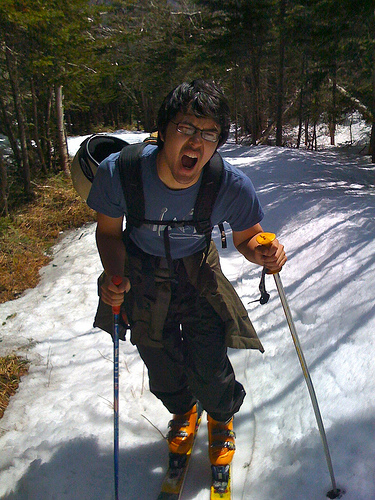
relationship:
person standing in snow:
[91, 68, 253, 443] [293, 194, 348, 256]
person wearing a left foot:
[91, 68, 253, 443] [204, 413, 235, 471]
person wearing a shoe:
[91, 68, 253, 443] [165, 385, 195, 462]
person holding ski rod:
[91, 68, 253, 443] [108, 280, 130, 496]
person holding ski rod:
[91, 68, 253, 443] [108, 272, 125, 498]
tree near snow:
[20, 60, 73, 169] [293, 194, 348, 256]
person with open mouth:
[91, 68, 253, 443] [177, 144, 200, 173]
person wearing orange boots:
[91, 68, 253, 443] [160, 391, 246, 469]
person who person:
[91, 68, 253, 443] [93, 76, 286, 470]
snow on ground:
[293, 194, 348, 256] [20, 217, 71, 280]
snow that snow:
[293, 194, 348, 256] [0, 217, 116, 499]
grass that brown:
[16, 180, 68, 261] [4, 361, 23, 388]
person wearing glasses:
[91, 68, 253, 443] [176, 118, 219, 143]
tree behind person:
[20, 60, 73, 169] [91, 68, 253, 443]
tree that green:
[20, 60, 73, 169] [28, 10, 49, 24]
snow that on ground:
[293, 194, 348, 256] [20, 217, 71, 280]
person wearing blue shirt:
[91, 68, 253, 443] [149, 188, 194, 248]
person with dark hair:
[91, 68, 253, 443] [180, 84, 216, 109]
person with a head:
[91, 68, 253, 443] [150, 82, 221, 179]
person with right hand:
[91, 68, 253, 443] [96, 267, 130, 306]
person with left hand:
[91, 68, 253, 443] [257, 227, 287, 272]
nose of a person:
[187, 132, 203, 150] [91, 68, 253, 443]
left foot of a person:
[208, 434, 239, 465] [91, 68, 253, 443]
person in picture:
[91, 68, 253, 443] [7, 32, 347, 478]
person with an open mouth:
[91, 68, 253, 443] [177, 144, 200, 173]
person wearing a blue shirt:
[91, 68, 253, 443] [149, 188, 194, 248]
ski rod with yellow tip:
[108, 272, 125, 498] [255, 229, 278, 244]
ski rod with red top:
[108, 280, 130, 496] [113, 276, 122, 313]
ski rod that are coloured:
[108, 272, 125, 498] [113, 306, 121, 340]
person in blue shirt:
[91, 68, 253, 443] [149, 188, 194, 248]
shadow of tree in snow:
[287, 149, 360, 197] [293, 194, 348, 256]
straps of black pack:
[120, 152, 147, 225] [137, 123, 162, 151]